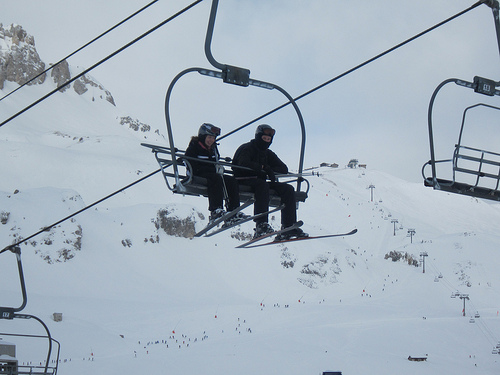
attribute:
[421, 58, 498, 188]
chair — empty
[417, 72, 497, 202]
lift — empty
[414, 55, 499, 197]
lift — empty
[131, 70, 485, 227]
lifts — metal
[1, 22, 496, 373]
mountain — rocky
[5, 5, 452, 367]
rocky snow — snow covered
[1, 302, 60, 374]
chair — empty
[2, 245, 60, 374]
lift — empty